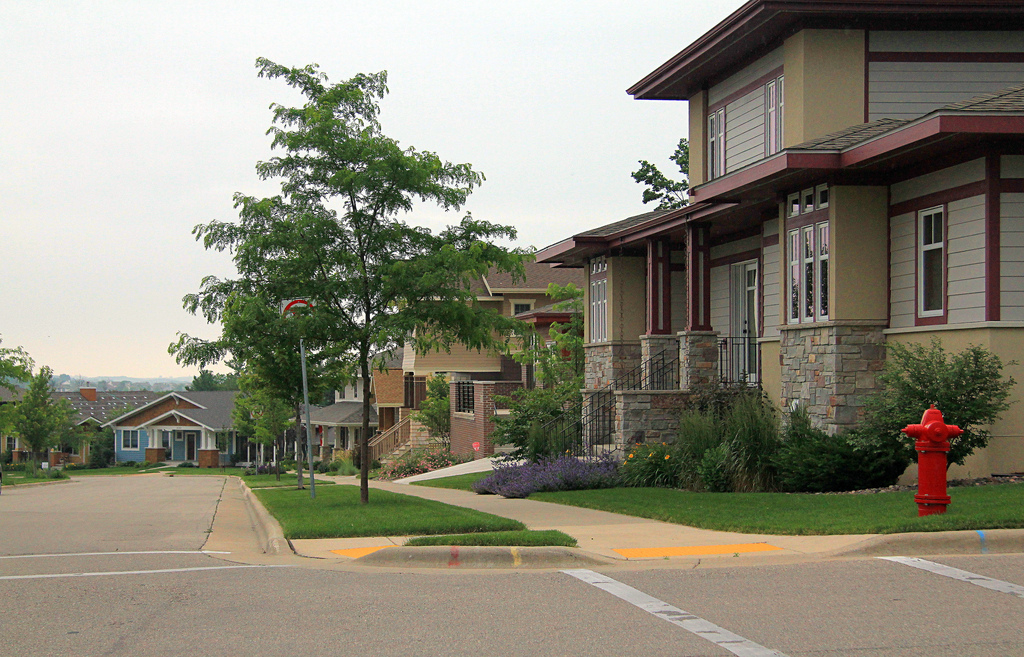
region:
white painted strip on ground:
[599, 529, 778, 559]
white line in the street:
[553, 564, 781, 651]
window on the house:
[906, 204, 961, 335]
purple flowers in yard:
[490, 453, 614, 498]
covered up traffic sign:
[269, 284, 330, 339]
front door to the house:
[738, 262, 765, 380]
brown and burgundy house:
[537, 11, 1022, 489]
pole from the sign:
[287, 336, 332, 496]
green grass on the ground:
[280, 488, 367, 533]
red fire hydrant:
[902, 402, 961, 511]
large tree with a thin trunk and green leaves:
[174, 59, 549, 513]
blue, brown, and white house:
[13, 388, 277, 484]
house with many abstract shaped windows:
[514, 3, 1018, 479]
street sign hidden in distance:
[276, 290, 337, 505]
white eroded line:
[541, 556, 801, 655]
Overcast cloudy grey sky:
[1, 6, 749, 389]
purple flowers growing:
[456, 440, 633, 505]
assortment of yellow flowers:
[612, 427, 688, 478]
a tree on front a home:
[187, 39, 760, 518]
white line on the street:
[558, 545, 743, 654]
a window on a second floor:
[685, 59, 799, 187]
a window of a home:
[773, 191, 847, 337]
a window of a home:
[111, 420, 147, 460]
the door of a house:
[179, 428, 203, 466]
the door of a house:
[721, 252, 772, 392]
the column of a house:
[673, 219, 728, 393]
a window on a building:
[909, 210, 963, 308]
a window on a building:
[813, 225, 833, 325]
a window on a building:
[796, 220, 815, 344]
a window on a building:
[779, 241, 806, 322]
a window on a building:
[734, 263, 750, 380]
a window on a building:
[504, 305, 544, 329]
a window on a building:
[330, 415, 353, 457]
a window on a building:
[219, 431, 238, 454]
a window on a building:
[186, 428, 191, 474]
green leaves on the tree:
[327, 274, 367, 355]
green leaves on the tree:
[298, 241, 365, 340]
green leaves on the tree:
[430, 186, 468, 247]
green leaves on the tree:
[310, 63, 400, 185]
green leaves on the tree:
[433, 303, 588, 408]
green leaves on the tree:
[310, 60, 400, 177]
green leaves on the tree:
[181, 183, 280, 311]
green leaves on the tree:
[225, 353, 257, 402]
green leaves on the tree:
[272, 303, 345, 381]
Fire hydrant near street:
[888, 401, 969, 518]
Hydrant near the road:
[871, 394, 970, 515]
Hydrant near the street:
[882, 408, 978, 516]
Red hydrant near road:
[863, 392, 974, 523]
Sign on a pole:
[252, 282, 361, 523]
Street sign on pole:
[249, 291, 352, 500]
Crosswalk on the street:
[547, 554, 1006, 654]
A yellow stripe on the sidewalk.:
[615, 541, 799, 571]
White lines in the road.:
[9, 521, 278, 594]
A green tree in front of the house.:
[252, 75, 484, 525]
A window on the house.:
[887, 214, 964, 331]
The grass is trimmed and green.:
[290, 458, 493, 548]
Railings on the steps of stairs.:
[533, 370, 644, 465]